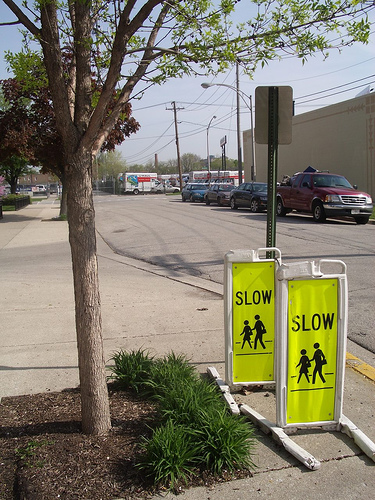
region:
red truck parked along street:
[264, 165, 373, 223]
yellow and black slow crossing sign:
[282, 280, 345, 425]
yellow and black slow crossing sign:
[232, 261, 277, 383]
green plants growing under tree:
[109, 341, 257, 492]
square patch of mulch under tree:
[2, 369, 250, 493]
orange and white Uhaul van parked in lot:
[118, 170, 159, 193]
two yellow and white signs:
[214, 223, 346, 438]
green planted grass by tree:
[114, 357, 239, 475]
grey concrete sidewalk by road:
[17, 239, 66, 364]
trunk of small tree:
[60, 204, 114, 461]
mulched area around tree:
[11, 395, 162, 479]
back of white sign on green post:
[247, 83, 296, 248]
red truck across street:
[267, 154, 358, 246]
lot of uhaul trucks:
[114, 150, 254, 197]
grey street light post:
[202, 77, 259, 156]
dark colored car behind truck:
[234, 185, 280, 231]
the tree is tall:
[23, 75, 158, 406]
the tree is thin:
[24, 174, 150, 364]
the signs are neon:
[205, 201, 321, 364]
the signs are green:
[232, 270, 324, 373]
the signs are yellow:
[205, 233, 333, 413]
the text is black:
[232, 296, 358, 403]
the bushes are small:
[142, 338, 242, 480]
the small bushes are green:
[139, 385, 205, 456]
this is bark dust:
[42, 431, 133, 467]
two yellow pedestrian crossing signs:
[207, 246, 374, 470]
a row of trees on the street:
[0, 0, 373, 434]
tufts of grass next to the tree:
[109, 350, 261, 482]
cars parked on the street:
[181, 172, 373, 225]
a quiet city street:
[93, 179, 374, 366]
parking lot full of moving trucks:
[114, 170, 245, 194]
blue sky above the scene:
[0, 0, 374, 169]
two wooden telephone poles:
[165, 48, 246, 192]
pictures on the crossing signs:
[238, 313, 327, 383]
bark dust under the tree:
[0, 380, 254, 498]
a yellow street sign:
[288, 279, 336, 419]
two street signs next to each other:
[222, 250, 344, 431]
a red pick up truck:
[274, 171, 371, 224]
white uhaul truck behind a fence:
[116, 171, 168, 193]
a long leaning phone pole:
[162, 99, 188, 198]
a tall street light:
[200, 76, 255, 196]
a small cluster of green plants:
[111, 348, 257, 491]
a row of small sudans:
[181, 173, 269, 210]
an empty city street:
[95, 191, 224, 296]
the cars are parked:
[167, 163, 372, 242]